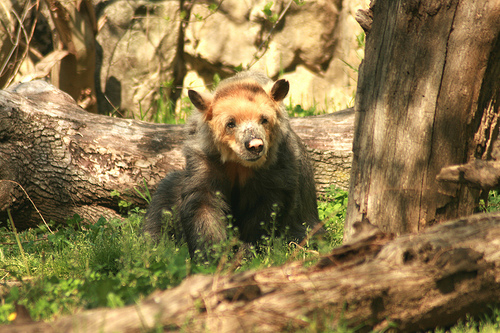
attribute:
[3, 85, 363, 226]
log — large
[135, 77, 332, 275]
bear — brown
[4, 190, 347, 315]
grass — tall